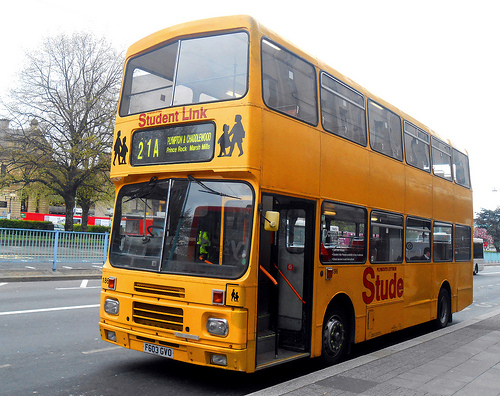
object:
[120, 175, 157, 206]
wipers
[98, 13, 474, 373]
bus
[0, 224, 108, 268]
fence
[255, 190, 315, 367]
door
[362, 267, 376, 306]
writing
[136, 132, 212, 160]
sign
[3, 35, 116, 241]
tree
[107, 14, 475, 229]
floor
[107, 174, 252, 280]
window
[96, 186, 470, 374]
levels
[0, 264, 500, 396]
road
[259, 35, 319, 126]
windows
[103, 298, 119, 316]
ligth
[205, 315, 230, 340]
light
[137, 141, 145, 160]
number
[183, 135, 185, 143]
lettering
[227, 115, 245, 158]
man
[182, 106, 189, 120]
words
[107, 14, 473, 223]
top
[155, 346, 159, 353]
numbers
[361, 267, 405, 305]
print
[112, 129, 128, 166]
graphic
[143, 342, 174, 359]
plate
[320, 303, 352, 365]
wheel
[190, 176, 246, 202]
blades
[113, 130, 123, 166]
children